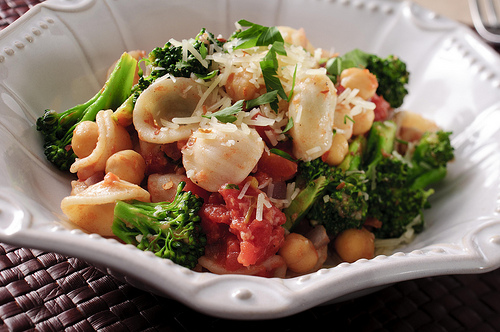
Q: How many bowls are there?
A: One.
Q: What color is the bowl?
A: White.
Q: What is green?
A: Broccoli.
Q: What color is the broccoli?
A: Green.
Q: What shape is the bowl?
A: Circle.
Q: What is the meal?
A: Salad.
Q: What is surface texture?
A: Weave.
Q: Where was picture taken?
A: At a restaurant.